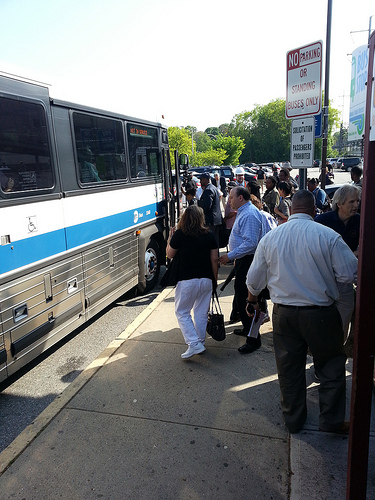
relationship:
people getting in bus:
[177, 173, 247, 237] [5, 60, 177, 390]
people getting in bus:
[166, 184, 361, 436] [5, 60, 177, 390]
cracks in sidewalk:
[98, 320, 292, 451] [27, 274, 373, 498]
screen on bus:
[125, 120, 159, 143] [5, 60, 177, 390]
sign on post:
[285, 39, 322, 119] [292, 108, 307, 218]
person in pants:
[166, 204, 219, 359] [174, 277, 212, 359]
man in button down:
[215, 184, 264, 354] [221, 202, 273, 272]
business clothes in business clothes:
[245, 189, 358, 435] [241, 216, 358, 428]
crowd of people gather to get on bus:
[176, 167, 363, 353] [5, 60, 177, 390]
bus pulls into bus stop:
[5, 60, 177, 390] [3, 212, 367, 489]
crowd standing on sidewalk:
[165, 162, 364, 434] [4, 209, 355, 496]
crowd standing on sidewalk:
[165, 162, 364, 434] [9, 263, 351, 496]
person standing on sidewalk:
[213, 168, 270, 362] [9, 263, 351, 496]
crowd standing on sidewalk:
[165, 162, 364, 434] [54, 332, 335, 450]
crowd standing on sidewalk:
[165, 162, 364, 434] [52, 306, 335, 479]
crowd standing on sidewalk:
[165, 162, 364, 434] [23, 310, 369, 492]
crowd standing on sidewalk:
[165, 162, 364, 434] [98, 287, 359, 496]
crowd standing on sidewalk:
[165, 162, 364, 434] [74, 308, 374, 494]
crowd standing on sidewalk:
[165, 162, 364, 434] [55, 295, 373, 487]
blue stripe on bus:
[83, 225, 101, 235] [5, 60, 177, 390]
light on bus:
[62, 279, 85, 291] [1, 67, 191, 427]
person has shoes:
[166, 204, 219, 359] [179, 341, 206, 360]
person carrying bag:
[166, 204, 219, 359] [205, 287, 226, 342]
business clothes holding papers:
[245, 189, 358, 435] [331, 226, 356, 329]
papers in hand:
[331, 226, 356, 329] [253, 288, 270, 301]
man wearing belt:
[220, 186, 262, 346] [228, 257, 255, 265]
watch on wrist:
[215, 254, 225, 266] [215, 244, 235, 267]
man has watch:
[215, 184, 264, 354] [215, 254, 225, 266]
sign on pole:
[274, 39, 331, 172] [320, 1, 332, 183]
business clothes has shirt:
[245, 189, 358, 435] [247, 216, 357, 317]